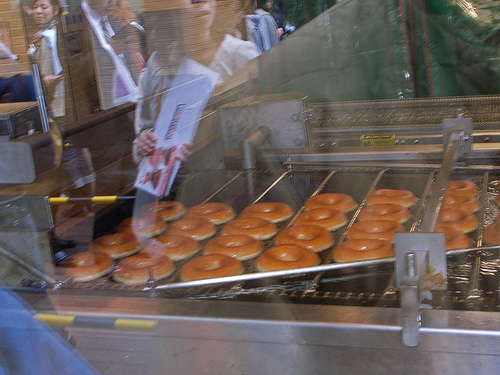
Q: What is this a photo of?
A: Donuts.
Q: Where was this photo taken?
A: A donut shop.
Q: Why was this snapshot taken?
A: For a magazine.